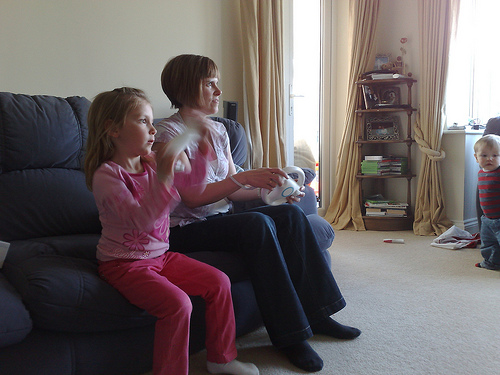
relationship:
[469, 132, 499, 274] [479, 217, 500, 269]
boy wearing jeans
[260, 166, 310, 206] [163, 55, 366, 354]
game controller being held by woman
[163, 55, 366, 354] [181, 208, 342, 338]
woman wearing blue jeans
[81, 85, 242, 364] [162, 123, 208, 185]
girl moving a game controller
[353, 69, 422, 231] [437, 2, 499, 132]
shelf next to a window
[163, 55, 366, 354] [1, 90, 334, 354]
woman sitting on couch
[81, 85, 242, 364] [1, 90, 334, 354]
girl sitting on couch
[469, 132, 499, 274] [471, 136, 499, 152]
boy has blond hair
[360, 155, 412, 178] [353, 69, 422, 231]
books are on shelf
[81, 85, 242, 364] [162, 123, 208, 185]
girl holding game controller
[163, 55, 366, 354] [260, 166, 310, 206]
woman holding game controller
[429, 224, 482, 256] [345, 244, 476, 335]
plastic bag on carpet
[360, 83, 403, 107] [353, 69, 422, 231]
framed pictures are on shelf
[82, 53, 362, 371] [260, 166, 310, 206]
two people have a game controller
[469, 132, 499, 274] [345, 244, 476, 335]
boy on carpet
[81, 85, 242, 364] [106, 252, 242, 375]
girl wearing pants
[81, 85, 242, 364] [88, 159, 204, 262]
girl wearing a top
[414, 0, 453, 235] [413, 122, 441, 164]
curtains are tied back with rope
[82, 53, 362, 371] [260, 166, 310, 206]
two people are playing with a game controller